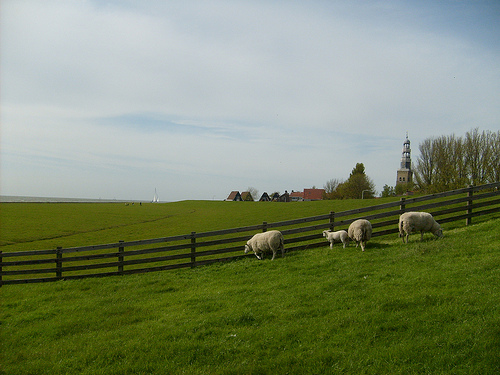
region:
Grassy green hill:
[124, 280, 402, 322]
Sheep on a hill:
[226, 200, 471, 269]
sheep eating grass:
[222, 202, 484, 269]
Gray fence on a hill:
[92, 200, 484, 292]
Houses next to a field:
[221, 163, 381, 232]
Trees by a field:
[416, 123, 499, 182]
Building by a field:
[386, 129, 447, 233]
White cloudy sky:
[36, 83, 249, 178]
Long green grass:
[87, 283, 284, 374]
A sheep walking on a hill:
[233, 225, 324, 262]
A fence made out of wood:
[0, 180, 499, 283]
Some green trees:
[413, 127, 498, 194]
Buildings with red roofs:
[288, 186, 325, 201]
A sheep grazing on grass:
[398, 210, 446, 244]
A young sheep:
[321, 229, 351, 250]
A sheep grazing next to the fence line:
[242, 228, 287, 260]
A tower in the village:
[397, 131, 412, 196]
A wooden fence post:
[56, 247, 62, 282]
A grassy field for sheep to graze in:
[1, 215, 498, 373]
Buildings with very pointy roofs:
[226, 190, 291, 199]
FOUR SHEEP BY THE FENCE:
[221, 203, 462, 265]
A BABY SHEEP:
[307, 223, 357, 253]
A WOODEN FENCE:
[30, 226, 220, 287]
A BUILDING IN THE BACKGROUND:
[391, 132, 422, 201]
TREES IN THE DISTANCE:
[414, 122, 497, 197]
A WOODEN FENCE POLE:
[111, 233, 131, 279]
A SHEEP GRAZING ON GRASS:
[387, 203, 469, 254]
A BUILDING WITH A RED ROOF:
[277, 182, 334, 209]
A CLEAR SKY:
[164, 43, 338, 134]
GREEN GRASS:
[98, 283, 335, 345]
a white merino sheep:
[393, 205, 444, 239]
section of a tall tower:
[399, 108, 412, 168]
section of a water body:
[11, 193, 59, 200]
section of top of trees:
[418, 128, 492, 163]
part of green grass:
[262, 277, 434, 354]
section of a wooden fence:
[105, 235, 192, 279]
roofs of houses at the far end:
[216, 185, 289, 206]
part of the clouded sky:
[96, 92, 225, 139]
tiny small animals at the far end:
[118, 198, 140, 203]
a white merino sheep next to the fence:
[243, 235, 284, 257]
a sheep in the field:
[240, 228, 287, 261]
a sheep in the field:
[318, 225, 348, 247]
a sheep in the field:
[346, 217, 372, 251]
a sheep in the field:
[395, 209, 442, 242]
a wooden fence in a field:
[1, 181, 498, 288]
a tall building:
[391, 126, 413, 189]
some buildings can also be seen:
[222, 183, 330, 202]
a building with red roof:
[306, 188, 323, 199]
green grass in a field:
[5, 195, 499, 372]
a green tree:
[345, 159, 371, 197]